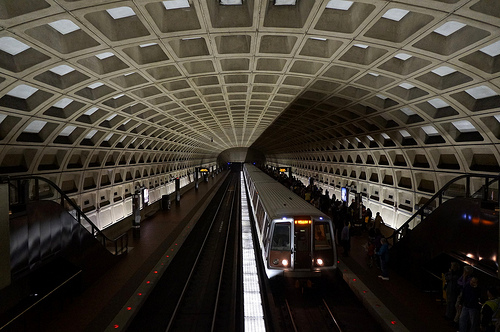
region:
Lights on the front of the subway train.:
[270, 258, 332, 266]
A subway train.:
[241, 161, 340, 282]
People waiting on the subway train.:
[254, 161, 394, 276]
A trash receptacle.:
[161, 193, 173, 210]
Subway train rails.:
[284, 275, 341, 328]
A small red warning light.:
[137, 290, 142, 294]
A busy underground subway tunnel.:
[2, 2, 497, 329]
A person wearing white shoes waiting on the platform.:
[372, 237, 391, 281]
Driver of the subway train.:
[314, 222, 330, 243]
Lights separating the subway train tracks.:
[239, 170, 265, 330]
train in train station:
[234, 157, 343, 275]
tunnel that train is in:
[7, 35, 499, 244]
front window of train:
[268, 218, 331, 267]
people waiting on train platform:
[265, 156, 392, 255]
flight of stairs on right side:
[360, 155, 494, 299]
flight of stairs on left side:
[10, 178, 140, 287]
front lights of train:
[282, 256, 324, 269]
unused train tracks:
[161, 158, 246, 325]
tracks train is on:
[261, 268, 369, 325]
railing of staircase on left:
[10, 161, 132, 255]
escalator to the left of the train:
[1, 180, 133, 301]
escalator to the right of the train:
[388, 170, 498, 267]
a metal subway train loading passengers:
[234, 152, 331, 284]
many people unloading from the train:
[281, 156, 378, 236]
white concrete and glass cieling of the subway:
[88, 76, 243, 155]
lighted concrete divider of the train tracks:
[226, 170, 261, 327]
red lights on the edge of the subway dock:
[116, 230, 184, 330]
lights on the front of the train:
[273, 254, 330, 269]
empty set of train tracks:
[173, 218, 235, 317]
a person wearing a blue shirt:
[374, 233, 399, 284]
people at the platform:
[285, 124, 372, 250]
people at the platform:
[278, 157, 398, 286]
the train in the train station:
[222, 136, 405, 329]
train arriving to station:
[241, 157, 348, 284]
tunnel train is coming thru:
[6, 38, 488, 288]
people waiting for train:
[254, 153, 400, 257]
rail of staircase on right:
[366, 170, 491, 242]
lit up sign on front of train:
[291, 216, 312, 229]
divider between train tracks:
[231, 167, 268, 330]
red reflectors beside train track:
[114, 248, 179, 322]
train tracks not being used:
[159, 158, 241, 320]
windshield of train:
[264, 220, 337, 269]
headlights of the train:
[282, 253, 326, 267]